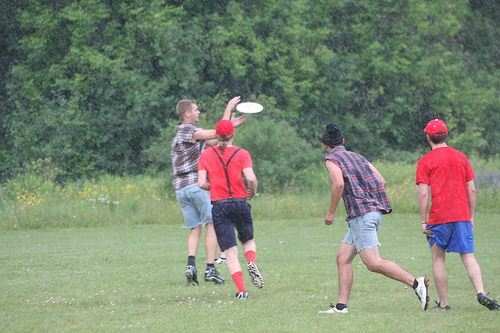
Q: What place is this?
A: It is a field.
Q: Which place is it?
A: It is a field.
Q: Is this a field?
A: Yes, it is a field.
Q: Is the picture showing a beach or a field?
A: It is showing a field.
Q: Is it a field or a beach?
A: It is a field.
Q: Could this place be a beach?
A: No, it is a field.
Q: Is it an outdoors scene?
A: Yes, it is outdoors.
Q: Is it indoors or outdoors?
A: It is outdoors.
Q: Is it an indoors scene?
A: No, it is outdoors.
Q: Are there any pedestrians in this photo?
A: No, there are no pedestrians.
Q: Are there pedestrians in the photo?
A: No, there are no pedestrians.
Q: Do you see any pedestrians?
A: No, there are no pedestrians.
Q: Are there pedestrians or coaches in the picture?
A: No, there are no pedestrians or coaches.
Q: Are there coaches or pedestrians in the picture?
A: No, there are no pedestrians or coaches.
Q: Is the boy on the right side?
A: Yes, the boy is on the right of the image.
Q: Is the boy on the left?
A: No, the boy is on the right of the image.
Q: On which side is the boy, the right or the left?
A: The boy is on the right of the image.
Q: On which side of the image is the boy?
A: The boy is on the right of the image.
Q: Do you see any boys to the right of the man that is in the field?
A: Yes, there is a boy to the right of the man.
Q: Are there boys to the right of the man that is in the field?
A: Yes, there is a boy to the right of the man.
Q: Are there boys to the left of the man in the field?
A: No, the boy is to the right of the man.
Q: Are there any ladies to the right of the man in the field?
A: No, there is a boy to the right of the man.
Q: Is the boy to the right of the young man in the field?
A: Yes, the boy is to the right of the man.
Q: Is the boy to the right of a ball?
A: No, the boy is to the right of the man.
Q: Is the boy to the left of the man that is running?
A: No, the boy is to the right of the man.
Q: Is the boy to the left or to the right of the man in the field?
A: The boy is to the right of the man.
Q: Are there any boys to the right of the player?
A: Yes, there is a boy to the right of the player.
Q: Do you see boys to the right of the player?
A: Yes, there is a boy to the right of the player.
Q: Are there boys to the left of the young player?
A: No, the boy is to the right of the player.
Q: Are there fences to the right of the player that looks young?
A: No, there is a boy to the right of the player.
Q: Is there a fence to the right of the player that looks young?
A: No, there is a boy to the right of the player.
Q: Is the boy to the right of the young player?
A: Yes, the boy is to the right of the player.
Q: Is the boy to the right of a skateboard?
A: No, the boy is to the right of the player.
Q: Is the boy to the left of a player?
A: No, the boy is to the right of a player.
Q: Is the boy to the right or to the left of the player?
A: The boy is to the right of the player.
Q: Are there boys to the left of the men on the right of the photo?
A: Yes, there is a boy to the left of the men.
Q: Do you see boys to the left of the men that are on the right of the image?
A: Yes, there is a boy to the left of the men.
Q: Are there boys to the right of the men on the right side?
A: No, the boy is to the left of the men.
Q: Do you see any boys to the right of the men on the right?
A: No, the boy is to the left of the men.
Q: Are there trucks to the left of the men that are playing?
A: No, there is a boy to the left of the men.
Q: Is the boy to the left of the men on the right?
A: Yes, the boy is to the left of the men.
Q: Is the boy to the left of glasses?
A: No, the boy is to the left of the men.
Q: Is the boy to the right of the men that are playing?
A: No, the boy is to the left of the men.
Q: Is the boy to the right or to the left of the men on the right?
A: The boy is to the left of the men.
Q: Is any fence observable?
A: No, there are no fences.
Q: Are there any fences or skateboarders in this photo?
A: No, there are no fences or skateboarders.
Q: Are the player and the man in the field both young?
A: Yes, both the player and the man are young.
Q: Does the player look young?
A: Yes, the player is young.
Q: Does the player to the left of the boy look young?
A: Yes, the player is young.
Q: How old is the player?
A: The player is young.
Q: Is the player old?
A: No, the player is young.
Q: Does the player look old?
A: No, the player is young.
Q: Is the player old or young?
A: The player is young.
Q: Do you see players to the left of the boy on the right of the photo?
A: Yes, there is a player to the left of the boy.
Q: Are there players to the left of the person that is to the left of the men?
A: Yes, there is a player to the left of the boy.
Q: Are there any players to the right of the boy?
A: No, the player is to the left of the boy.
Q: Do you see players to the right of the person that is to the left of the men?
A: No, the player is to the left of the boy.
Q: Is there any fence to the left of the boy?
A: No, there is a player to the left of the boy.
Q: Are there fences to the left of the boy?
A: No, there is a player to the left of the boy.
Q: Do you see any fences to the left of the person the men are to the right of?
A: No, there is a player to the left of the boy.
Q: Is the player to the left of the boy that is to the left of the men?
A: Yes, the player is to the left of the boy.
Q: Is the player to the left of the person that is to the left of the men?
A: Yes, the player is to the left of the boy.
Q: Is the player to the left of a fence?
A: No, the player is to the left of the boy.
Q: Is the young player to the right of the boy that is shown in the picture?
A: No, the player is to the left of the boy.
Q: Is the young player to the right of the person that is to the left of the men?
A: No, the player is to the left of the boy.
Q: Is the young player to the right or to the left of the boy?
A: The player is to the left of the boy.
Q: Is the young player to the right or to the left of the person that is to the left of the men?
A: The player is to the left of the boy.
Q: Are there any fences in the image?
A: No, there are no fences.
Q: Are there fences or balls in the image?
A: No, there are no fences or balls.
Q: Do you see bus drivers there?
A: No, there are no bus drivers.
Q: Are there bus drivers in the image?
A: No, there are no bus drivers.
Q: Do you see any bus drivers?
A: No, there are no bus drivers.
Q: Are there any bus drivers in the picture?
A: No, there are no bus drivers.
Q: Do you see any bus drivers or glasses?
A: No, there are no bus drivers or glasses.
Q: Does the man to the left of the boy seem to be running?
A: Yes, the man is running.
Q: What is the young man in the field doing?
A: The man is running.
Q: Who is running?
A: The man is running.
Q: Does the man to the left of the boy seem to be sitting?
A: No, the man is running.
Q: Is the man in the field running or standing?
A: The man is running.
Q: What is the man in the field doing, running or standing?
A: The man is running.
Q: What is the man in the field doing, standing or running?
A: The man is running.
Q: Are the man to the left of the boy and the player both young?
A: Yes, both the man and the player are young.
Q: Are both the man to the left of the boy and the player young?
A: Yes, both the man and the player are young.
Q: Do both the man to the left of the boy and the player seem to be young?
A: Yes, both the man and the player are young.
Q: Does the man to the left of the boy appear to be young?
A: Yes, the man is young.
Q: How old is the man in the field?
A: The man is young.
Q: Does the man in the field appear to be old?
A: No, the man is young.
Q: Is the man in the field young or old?
A: The man is young.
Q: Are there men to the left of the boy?
A: Yes, there is a man to the left of the boy.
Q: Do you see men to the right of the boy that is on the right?
A: No, the man is to the left of the boy.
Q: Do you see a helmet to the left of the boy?
A: No, there is a man to the left of the boy.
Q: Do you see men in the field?
A: Yes, there is a man in the field.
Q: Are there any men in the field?
A: Yes, there is a man in the field.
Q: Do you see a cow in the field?
A: No, there is a man in the field.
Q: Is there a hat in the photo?
A: Yes, there is a hat.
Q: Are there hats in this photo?
A: Yes, there is a hat.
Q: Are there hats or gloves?
A: Yes, there is a hat.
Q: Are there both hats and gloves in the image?
A: No, there is a hat but no gloves.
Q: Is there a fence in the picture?
A: No, there are no fences.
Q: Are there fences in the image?
A: No, there are no fences.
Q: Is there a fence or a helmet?
A: No, there are no fences or helmets.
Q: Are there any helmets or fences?
A: No, there are no fences or helmets.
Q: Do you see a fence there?
A: No, there are no fences.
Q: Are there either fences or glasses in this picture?
A: No, there are no fences or glasses.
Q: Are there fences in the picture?
A: No, there are no fences.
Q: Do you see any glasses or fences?
A: No, there are no fences or glasses.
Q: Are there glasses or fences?
A: No, there are no fences or glasses.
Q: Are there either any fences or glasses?
A: No, there are no fences or glasses.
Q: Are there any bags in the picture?
A: No, there are no bags.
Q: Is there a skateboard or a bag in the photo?
A: No, there are no bags or skateboards.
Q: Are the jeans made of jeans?
A: Yes, the jeans are made of jeans.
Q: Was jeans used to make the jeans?
A: Yes, the jeans are made of jeans.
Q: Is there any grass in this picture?
A: Yes, there is grass.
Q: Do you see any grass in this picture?
A: Yes, there is grass.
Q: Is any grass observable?
A: Yes, there is grass.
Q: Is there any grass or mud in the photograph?
A: Yes, there is grass.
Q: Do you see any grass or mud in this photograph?
A: Yes, there is grass.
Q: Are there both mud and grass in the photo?
A: No, there is grass but no mud.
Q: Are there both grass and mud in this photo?
A: No, there is grass but no mud.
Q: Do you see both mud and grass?
A: No, there is grass but no mud.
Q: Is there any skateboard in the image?
A: No, there are no skateboards.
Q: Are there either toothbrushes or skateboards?
A: No, there are no skateboards or toothbrushes.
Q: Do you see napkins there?
A: No, there are no napkins.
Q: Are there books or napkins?
A: No, there are no napkins or books.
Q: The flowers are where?
A: The flowers are on the field.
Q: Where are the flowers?
A: The flowers are on the field.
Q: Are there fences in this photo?
A: No, there are no fences.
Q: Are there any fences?
A: No, there are no fences.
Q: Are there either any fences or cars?
A: No, there are no fences or cars.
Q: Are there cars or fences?
A: No, there are no fences or cars.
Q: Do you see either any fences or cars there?
A: No, there are no fences or cars.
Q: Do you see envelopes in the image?
A: No, there are no envelopes.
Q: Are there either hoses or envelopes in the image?
A: No, there are no envelopes or hoses.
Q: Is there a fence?
A: No, there are no fences.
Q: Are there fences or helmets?
A: No, there are no fences or helmets.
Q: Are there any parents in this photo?
A: No, there are no parents.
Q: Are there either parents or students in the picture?
A: No, there are no parents or students.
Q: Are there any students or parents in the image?
A: No, there are no parents or students.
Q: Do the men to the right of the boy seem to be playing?
A: Yes, the men are playing.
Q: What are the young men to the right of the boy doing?
A: The men are playing.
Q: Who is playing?
A: The men are playing.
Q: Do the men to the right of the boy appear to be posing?
A: No, the men are playing.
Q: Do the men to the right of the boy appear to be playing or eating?
A: The men are playing.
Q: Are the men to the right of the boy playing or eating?
A: The men are playing.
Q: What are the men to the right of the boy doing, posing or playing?
A: The men are playing.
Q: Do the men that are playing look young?
A: Yes, the men are young.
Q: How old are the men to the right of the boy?
A: The men are young.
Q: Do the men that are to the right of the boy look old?
A: No, the men are young.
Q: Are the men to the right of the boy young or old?
A: The men are young.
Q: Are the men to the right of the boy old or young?
A: The men are young.